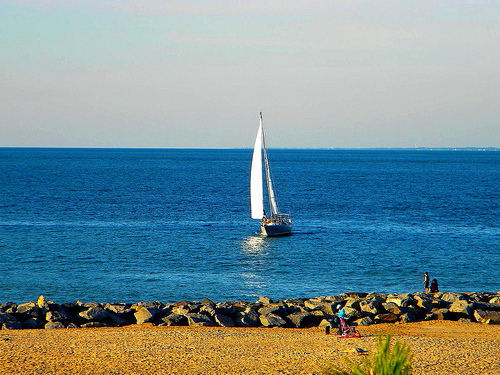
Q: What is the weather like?
A: It is cloudy.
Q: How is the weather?
A: It is cloudy.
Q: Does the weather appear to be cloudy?
A: Yes, it is cloudy.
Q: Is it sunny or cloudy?
A: It is cloudy.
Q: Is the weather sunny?
A: No, it is cloudy.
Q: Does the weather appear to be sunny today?
A: No, it is cloudy.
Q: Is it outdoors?
A: Yes, it is outdoors.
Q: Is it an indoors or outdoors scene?
A: It is outdoors.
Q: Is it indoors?
A: No, it is outdoors.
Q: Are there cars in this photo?
A: No, there are no cars.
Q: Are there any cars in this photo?
A: No, there are no cars.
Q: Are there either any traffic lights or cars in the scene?
A: No, there are no cars or traffic lights.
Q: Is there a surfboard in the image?
A: No, there are no surfboards.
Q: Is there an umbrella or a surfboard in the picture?
A: No, there are no surfboards or umbrellas.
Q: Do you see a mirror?
A: No, there are no mirrors.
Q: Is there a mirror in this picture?
A: No, there are no mirrors.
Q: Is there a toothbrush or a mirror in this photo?
A: No, there are no mirrors or toothbrushes.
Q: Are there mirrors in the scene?
A: No, there are no mirrors.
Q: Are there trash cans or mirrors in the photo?
A: No, there are no mirrors or trash cans.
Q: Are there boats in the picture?
A: Yes, there is a boat.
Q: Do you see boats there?
A: Yes, there is a boat.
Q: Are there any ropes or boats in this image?
A: Yes, there is a boat.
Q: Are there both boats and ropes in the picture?
A: No, there is a boat but no ropes.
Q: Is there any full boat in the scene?
A: Yes, there is a full boat.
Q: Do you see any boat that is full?
A: Yes, there is a boat that is full.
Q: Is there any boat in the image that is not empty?
A: Yes, there is an full boat.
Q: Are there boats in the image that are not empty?
A: Yes, there is an full boat.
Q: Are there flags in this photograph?
A: No, there are no flags.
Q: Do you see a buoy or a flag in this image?
A: No, there are no flags or buoys.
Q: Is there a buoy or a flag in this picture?
A: No, there are no flags or buoys.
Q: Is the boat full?
A: Yes, the boat is full.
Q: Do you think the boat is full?
A: Yes, the boat is full.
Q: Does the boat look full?
A: Yes, the boat is full.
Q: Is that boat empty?
A: No, the boat is full.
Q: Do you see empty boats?
A: No, there is a boat but it is full.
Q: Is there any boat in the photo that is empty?
A: No, there is a boat but it is full.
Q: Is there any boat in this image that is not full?
A: No, there is a boat but it is full.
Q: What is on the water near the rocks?
A: The boat is on the water.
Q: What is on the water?
A: The boat is on the water.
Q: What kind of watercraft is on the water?
A: The watercraft is a boat.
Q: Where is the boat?
A: The boat is on the water.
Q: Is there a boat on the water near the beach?
A: Yes, there is a boat on the water.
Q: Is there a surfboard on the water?
A: No, there is a boat on the water.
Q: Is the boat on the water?
A: Yes, the boat is on the water.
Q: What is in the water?
A: The boat is in the water.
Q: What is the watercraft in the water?
A: The watercraft is a boat.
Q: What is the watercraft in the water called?
A: The watercraft is a boat.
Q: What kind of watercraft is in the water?
A: The watercraft is a boat.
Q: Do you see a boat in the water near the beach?
A: Yes, there is a boat in the water.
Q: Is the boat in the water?
A: Yes, the boat is in the water.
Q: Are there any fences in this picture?
A: No, there are no fences.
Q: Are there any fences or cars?
A: No, there are no fences or cars.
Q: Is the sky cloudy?
A: Yes, the sky is cloudy.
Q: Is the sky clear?
A: No, the sky is cloudy.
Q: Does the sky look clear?
A: No, the sky is cloudy.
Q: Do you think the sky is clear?
A: No, the sky is cloudy.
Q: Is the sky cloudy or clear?
A: The sky is cloudy.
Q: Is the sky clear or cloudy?
A: The sky is cloudy.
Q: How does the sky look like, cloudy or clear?
A: The sky is cloudy.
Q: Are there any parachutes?
A: No, there are no parachutes.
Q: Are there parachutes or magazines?
A: No, there are no parachutes or magazines.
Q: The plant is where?
A: The plant is on the beach.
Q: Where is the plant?
A: The plant is on the beach.